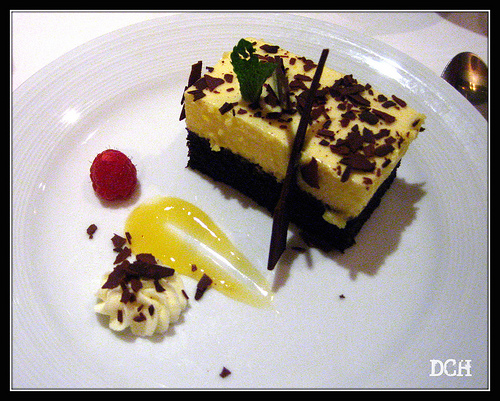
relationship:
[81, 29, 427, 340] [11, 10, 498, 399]
dessert served on plate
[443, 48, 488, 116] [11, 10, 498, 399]
spoon on side of plate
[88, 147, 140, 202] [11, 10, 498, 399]
raspberry served on plate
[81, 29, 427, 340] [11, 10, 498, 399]
dessert on top of plate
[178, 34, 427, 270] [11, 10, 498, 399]
cake on top of plate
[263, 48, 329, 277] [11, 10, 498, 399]
shaving on top of plate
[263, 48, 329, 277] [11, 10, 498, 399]
shaving on plate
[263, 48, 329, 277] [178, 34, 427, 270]
shaving in cake